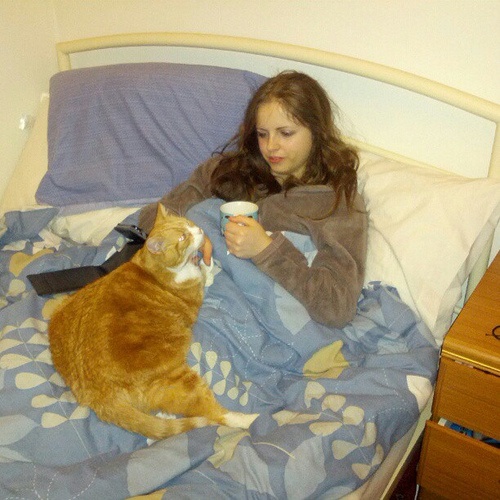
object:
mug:
[217, 197, 261, 238]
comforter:
[0, 193, 443, 498]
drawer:
[414, 418, 500, 500]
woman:
[135, 67, 368, 330]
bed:
[0, 26, 500, 500]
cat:
[45, 198, 261, 446]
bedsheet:
[354, 147, 500, 414]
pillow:
[33, 58, 270, 211]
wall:
[0, 0, 61, 197]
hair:
[209, 65, 368, 221]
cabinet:
[414, 249, 500, 499]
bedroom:
[0, 0, 499, 499]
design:
[302, 378, 327, 409]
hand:
[221, 213, 269, 259]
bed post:
[54, 28, 499, 123]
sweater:
[137, 149, 370, 332]